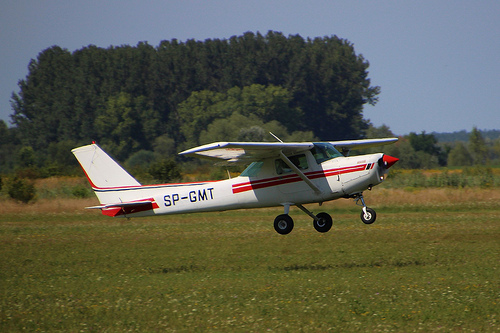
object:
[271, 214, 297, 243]
wheel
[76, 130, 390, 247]
plane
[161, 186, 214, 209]
letter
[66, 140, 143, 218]
tail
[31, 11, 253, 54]
sky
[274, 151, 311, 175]
window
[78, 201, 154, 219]
wing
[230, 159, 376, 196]
line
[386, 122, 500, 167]
trees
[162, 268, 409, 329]
flower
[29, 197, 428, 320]
grass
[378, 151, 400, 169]
nose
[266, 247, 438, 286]
shadow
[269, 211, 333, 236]
gear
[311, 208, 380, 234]
wheels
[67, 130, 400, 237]
airplane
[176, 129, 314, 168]
wings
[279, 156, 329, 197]
struts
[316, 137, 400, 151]
wing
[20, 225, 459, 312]
field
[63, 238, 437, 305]
ground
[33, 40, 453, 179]
forest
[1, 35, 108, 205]
tree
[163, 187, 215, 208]
writing